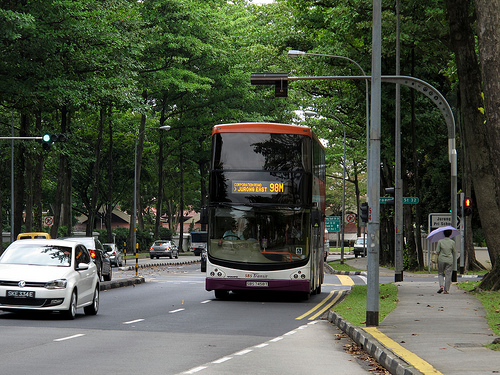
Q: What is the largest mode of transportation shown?
A: Double decker bus.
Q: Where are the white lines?
A: On the road.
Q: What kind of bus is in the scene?
A: Double decker.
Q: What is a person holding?
A: An umbrella.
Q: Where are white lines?
A: On the road.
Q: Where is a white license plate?
A: On front of bus.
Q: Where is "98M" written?
A: On the bus.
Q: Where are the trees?
A: On both sides of the road.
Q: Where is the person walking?
A: On the sidewalk.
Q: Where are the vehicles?
A: On the road.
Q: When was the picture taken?
A: During the daytime.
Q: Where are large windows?
A: On front of the bus.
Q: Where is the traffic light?
A: On the pole.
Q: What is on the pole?
A: A traffic light.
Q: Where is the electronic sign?
A: On the bus.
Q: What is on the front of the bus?
A: An electronic sign.